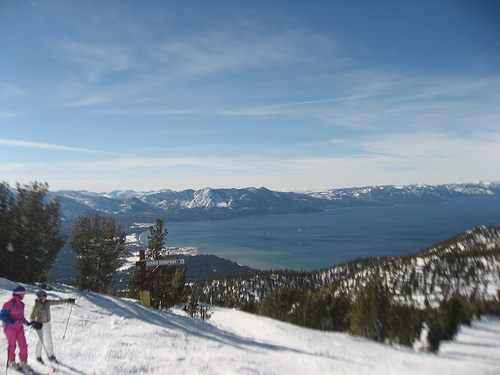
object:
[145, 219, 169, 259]
tree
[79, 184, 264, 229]
distance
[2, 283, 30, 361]
women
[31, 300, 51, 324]
jackets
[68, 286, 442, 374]
slope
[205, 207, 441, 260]
ocean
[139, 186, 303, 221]
mountains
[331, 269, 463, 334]
forest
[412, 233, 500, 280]
hill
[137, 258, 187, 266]
sign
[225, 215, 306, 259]
water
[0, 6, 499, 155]
sky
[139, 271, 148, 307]
pole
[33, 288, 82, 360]
woman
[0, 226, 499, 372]
mountain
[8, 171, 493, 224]
horizon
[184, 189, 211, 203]
snow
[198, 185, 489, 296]
out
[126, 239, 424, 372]
mountainside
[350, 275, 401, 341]
trees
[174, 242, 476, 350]
slopes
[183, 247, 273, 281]
beach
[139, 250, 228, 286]
bottom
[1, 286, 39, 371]
skier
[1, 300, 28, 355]
pink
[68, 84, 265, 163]
clouds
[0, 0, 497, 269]
background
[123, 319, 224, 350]
snow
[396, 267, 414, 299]
snow